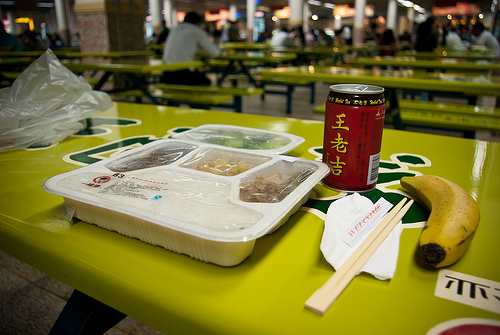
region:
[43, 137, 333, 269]
frozen dinner in tray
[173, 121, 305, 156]
frozen side dish in tray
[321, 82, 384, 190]
canned beverage with writing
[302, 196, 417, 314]
unwrapped and intact chopsticks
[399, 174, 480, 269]
ripe and unpeeled banana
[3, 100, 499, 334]
lime green restaurant table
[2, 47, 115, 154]
clear plastic bag on table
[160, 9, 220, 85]
man eating alone in food court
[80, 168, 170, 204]
heating instructions and warning label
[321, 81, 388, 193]
red and black can with yellow writing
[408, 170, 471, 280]
banana is yellow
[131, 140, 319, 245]
the package is white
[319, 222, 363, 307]
the chopsticks are made of wood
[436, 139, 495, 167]
the bench is green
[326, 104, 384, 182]
the can is red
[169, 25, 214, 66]
the shirt is white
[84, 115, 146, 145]
the table has graphic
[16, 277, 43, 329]
the floor has tiles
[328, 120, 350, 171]
the can has chinese writing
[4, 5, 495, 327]
it as a daytime photo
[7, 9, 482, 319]
Food at on a cafeteria table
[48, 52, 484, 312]
Lunch inside of a white container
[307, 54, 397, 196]
can of soda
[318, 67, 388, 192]
soda can is red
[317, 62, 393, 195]
soda can has gold Chines characters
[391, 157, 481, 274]
banana is yellow with brown specks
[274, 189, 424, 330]
chopsticks made of wood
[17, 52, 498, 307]
food is sitting on a bright lime green table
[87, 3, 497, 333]
A man is sitting in the background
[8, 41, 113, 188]
empty clear plastic bag next to food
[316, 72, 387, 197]
A red can is sitting on a table.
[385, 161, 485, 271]
A banana is sitting on a table.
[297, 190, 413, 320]
Two chopsticks are sitting on a table.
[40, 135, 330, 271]
A package of food is sitting on a table.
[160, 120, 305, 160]
A smaller package of food is sitting on a table.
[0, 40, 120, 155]
Plastic is sitting on a table.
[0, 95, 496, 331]
The table's colors are yellow, green, and red.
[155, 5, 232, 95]
A man is sitting at a table.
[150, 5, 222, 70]
A man is wearing a white shirt.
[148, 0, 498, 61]
A group of people are in the background.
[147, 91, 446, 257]
food on a table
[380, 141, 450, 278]
a banana on a table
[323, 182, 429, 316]
chopsticks on a napkin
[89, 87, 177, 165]
a green table with green writing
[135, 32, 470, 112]
people sitting at green tables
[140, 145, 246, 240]
food in separate compartments.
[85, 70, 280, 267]
food covered in plastic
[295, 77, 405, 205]
a drink sitting on a table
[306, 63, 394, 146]
a drink in a red can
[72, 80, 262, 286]
food in a white container